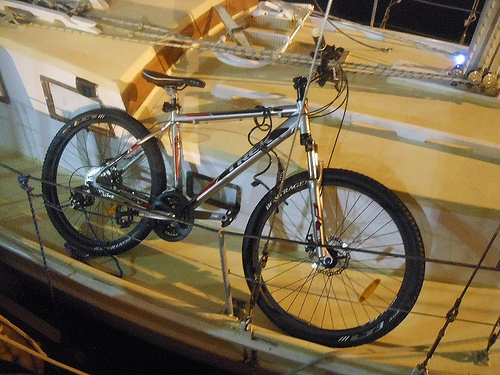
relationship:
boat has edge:
[1, 2, 499, 374] [0, 231, 416, 373]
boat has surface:
[1, 2, 499, 374] [0, 0, 498, 372]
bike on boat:
[38, 26, 427, 350] [1, 2, 499, 374]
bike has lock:
[38, 26, 427, 350] [250, 103, 285, 201]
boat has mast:
[1, 2, 499, 374] [456, 2, 499, 94]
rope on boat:
[0, 3, 497, 89] [1, 2, 499, 374]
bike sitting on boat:
[38, 26, 427, 350] [1, 2, 499, 374]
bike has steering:
[38, 26, 427, 350] [295, 28, 349, 86]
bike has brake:
[38, 26, 427, 350] [302, 61, 351, 258]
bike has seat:
[38, 26, 427, 350] [140, 67, 207, 90]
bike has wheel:
[38, 26, 427, 350] [240, 165, 425, 349]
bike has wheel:
[38, 26, 427, 350] [42, 107, 166, 254]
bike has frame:
[38, 26, 427, 350] [92, 78, 331, 268]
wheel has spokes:
[240, 165, 425, 349] [255, 185, 406, 331]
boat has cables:
[1, 2, 499, 374] [0, 164, 498, 375]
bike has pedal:
[38, 26, 427, 350] [218, 203, 242, 231]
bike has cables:
[38, 26, 427, 350] [299, 63, 351, 244]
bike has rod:
[38, 26, 427, 350] [190, 113, 301, 210]